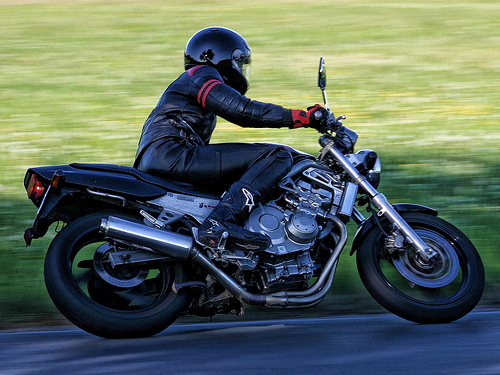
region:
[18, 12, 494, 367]
Person riding a motorcycle.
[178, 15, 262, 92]
A black motorcycle helmet.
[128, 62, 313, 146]
A black leather jacket.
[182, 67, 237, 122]
Red stripe on leather jacket.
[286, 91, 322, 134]
Red and black motorcycle glove.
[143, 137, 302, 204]
A pair of black leather pants.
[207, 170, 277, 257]
Black motorcycle boot on right leg.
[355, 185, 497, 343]
Front wheel of motorcycle.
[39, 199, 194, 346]
Rear wheel of motorcycle.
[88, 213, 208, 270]
Silver muffler on motorcycle.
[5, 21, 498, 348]
person riding a motorcycle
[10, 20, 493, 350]
person turning a mortorcycle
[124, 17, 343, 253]
motorcyclist wearing a black and red leather jacket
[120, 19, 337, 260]
motorcyclist wearing a black helmet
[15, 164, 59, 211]
illuminated red motorcycle tail light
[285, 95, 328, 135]
red and black leather glove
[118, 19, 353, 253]
motorcyclist wearing black leather pants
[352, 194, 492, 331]
black front motorcycle wheel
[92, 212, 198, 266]
metallic silver motorcycle tail pipe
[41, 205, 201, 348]
black rear motorcycle wheel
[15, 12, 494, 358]
man riding on motorcycle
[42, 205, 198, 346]
black motorcycle tire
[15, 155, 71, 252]
rear brake light of motorcycle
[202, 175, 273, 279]
black leather motorcycle boots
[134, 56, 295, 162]
black leather jacket with red stripes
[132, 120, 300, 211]
black leather pants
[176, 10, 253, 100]
black motorcycle helmet with face shield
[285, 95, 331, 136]
hand in red leather glove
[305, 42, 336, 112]
rearview mirror on handle bar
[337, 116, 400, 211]
head light of motorcycle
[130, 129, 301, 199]
shiny black leather pants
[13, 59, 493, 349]
black and silver motor cycle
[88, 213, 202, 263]
shiny silver exhaust pipe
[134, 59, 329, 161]
red and black leather jacket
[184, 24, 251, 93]
shiny black helmet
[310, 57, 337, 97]
shiny silver rear view mirror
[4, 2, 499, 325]
blurry green vegetation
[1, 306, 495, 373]
blurry black paved tarmac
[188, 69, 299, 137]
ribbed leather jacket sleeve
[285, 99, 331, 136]
red and black gloves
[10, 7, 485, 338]
a man riding a motorcycle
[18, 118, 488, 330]
a black motorcycle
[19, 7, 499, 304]
a grassy field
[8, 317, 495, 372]
an asphalt road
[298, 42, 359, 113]
side mirror on the bike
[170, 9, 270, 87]
a black motorcycle helmet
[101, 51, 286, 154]
a black leather jacket on the man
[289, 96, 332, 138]
a red glove on the man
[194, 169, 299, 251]
a black leather boot on the man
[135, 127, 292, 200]
some black leather pants on the man